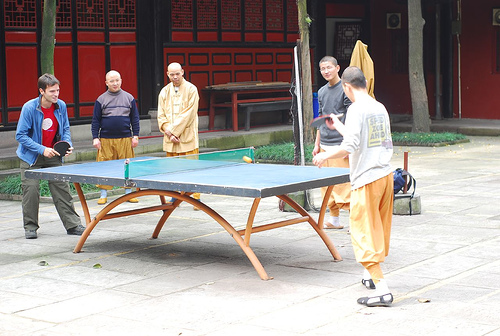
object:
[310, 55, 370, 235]
man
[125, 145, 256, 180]
table tennis net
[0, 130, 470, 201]
grass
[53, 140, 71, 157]
tennis paddle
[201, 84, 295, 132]
table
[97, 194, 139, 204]
sandles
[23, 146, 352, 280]
tennis table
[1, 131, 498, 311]
ground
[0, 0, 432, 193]
tree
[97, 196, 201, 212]
shoe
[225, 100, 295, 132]
bench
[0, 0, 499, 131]
wall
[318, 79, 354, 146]
shirt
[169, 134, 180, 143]
hand